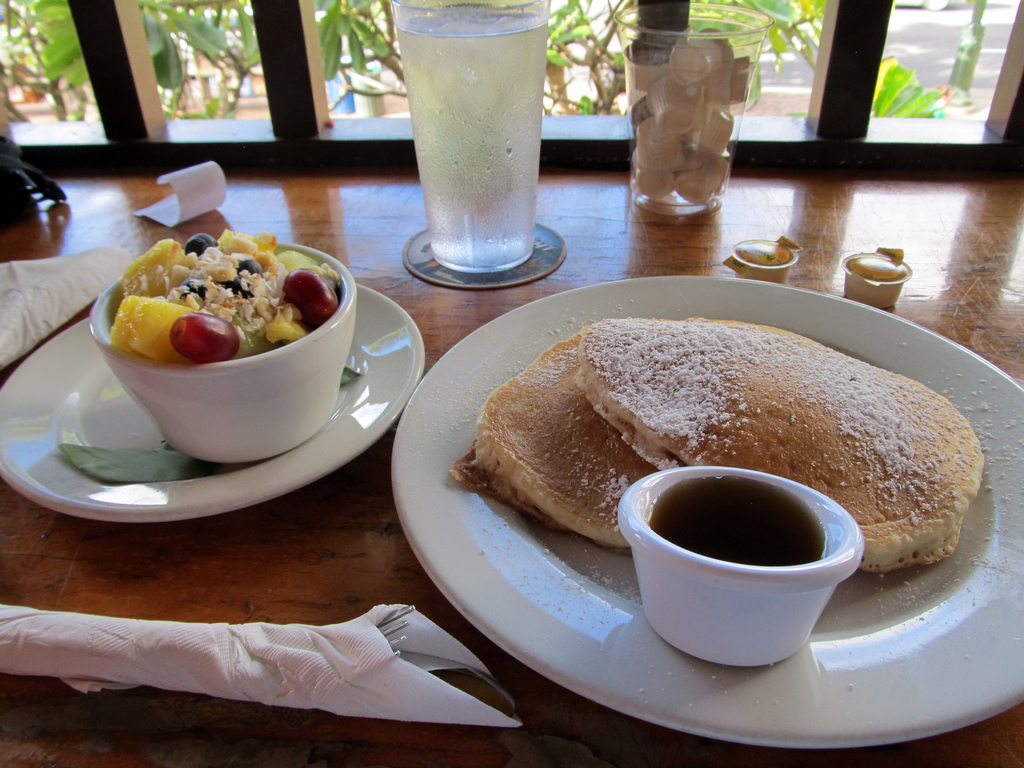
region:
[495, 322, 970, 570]
the pancake has powdered sugar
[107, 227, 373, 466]
the cup has fruits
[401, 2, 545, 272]
the glass has water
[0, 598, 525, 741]
the fork is in tissue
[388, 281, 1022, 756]
the plate is white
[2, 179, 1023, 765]
the table is made of wood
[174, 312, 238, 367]
the grape is red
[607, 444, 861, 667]
white cup of syrup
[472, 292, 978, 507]
pancakes dusted with powdered sugar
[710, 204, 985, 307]
two containers of margarine for pancakes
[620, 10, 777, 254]
cup filled with non-dairy creamers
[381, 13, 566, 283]
full glass of ice water on coaster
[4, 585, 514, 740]
silverware wrapped in white paper napkin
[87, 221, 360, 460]
mixed fruit in white ceramic cup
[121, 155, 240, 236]
white paper wrapper from silverware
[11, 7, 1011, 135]
view through window of sunny day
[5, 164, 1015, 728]
wooden table with breakfast foods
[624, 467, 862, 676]
Little white container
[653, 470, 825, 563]
Maple syrup for pancakes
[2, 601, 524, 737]
Fork and knife wrapped in napkin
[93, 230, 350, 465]
Fruit salad with granola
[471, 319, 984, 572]
Two pancakes on the plate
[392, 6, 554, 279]
Tall glass of water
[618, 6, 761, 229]
Glass with creamer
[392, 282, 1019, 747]
Plate with pancakes and syrup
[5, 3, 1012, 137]
Plants are right outside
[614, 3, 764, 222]
a plastic cup filled with butter cups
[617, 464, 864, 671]
a white bowl filled with syrup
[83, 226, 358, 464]
a white ceramic cup of fruit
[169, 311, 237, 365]
a purple and red grape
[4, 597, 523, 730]
silverware rolled in a napkin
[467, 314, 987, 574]
a stack of pancakes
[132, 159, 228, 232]
a curled paper silverware holder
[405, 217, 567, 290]
a round paper coaster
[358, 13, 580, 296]
glass on the table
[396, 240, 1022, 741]
a white dinner plate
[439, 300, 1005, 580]
a pair of pancakes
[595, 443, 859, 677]
a bowl of syrup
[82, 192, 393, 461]
a bowl of fruit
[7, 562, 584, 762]
a set of silverwater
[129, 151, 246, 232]
a piece of paper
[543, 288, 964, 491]
powder sugar on pancakes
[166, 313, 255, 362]
A piece of food.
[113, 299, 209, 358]
A piece of food.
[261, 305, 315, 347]
A piece of food.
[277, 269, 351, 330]
A piece of food.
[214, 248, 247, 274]
A piece of food.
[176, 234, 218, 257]
A piece of food.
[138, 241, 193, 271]
A piece of food.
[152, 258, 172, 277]
A piece of food.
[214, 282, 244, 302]
A piece of food.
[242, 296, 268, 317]
A piece of food.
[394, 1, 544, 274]
glass of ice water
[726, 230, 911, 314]
empty coffee creamer cups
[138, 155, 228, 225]
small piece of folded paper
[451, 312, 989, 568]
pancakes with white powder on top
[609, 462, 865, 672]
small white cup filled with syrup